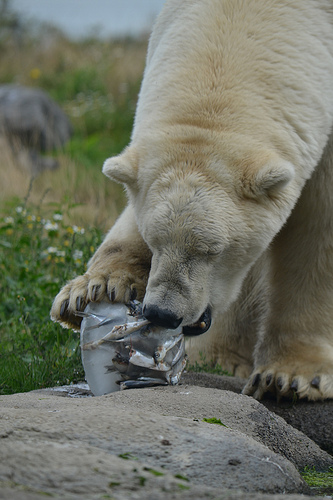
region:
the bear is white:
[59, 5, 314, 314]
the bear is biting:
[38, 228, 236, 390]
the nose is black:
[140, 297, 182, 334]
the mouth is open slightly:
[122, 284, 234, 349]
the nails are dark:
[42, 263, 140, 341]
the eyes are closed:
[109, 219, 235, 277]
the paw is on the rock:
[227, 340, 327, 415]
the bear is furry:
[113, 5, 302, 283]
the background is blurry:
[13, 8, 132, 146]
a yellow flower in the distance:
[9, 51, 57, 89]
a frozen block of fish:
[78, 301, 193, 394]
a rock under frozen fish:
[1, 371, 332, 498]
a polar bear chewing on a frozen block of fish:
[49, 5, 330, 396]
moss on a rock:
[200, 414, 228, 429]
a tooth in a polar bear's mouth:
[199, 319, 209, 331]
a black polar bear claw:
[87, 283, 101, 302]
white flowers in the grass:
[43, 210, 86, 257]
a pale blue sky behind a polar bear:
[7, 1, 166, 37]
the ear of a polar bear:
[97, 148, 141, 187]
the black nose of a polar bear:
[140, 301, 183, 328]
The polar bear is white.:
[45, 11, 325, 389]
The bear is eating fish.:
[43, 266, 235, 432]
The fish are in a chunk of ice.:
[48, 276, 224, 422]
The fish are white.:
[75, 263, 210, 429]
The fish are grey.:
[47, 265, 213, 437]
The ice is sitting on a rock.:
[12, 352, 326, 488]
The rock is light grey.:
[14, 374, 321, 499]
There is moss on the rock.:
[281, 440, 329, 498]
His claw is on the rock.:
[217, 362, 330, 405]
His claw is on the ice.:
[28, 267, 172, 330]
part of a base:
[97, 370, 122, 395]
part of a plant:
[302, 459, 320, 484]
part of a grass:
[33, 349, 74, 396]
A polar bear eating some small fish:
[42, 35, 332, 490]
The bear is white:
[78, 7, 311, 388]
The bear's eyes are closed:
[137, 230, 243, 280]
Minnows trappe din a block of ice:
[80, 293, 188, 393]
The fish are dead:
[102, 314, 188, 399]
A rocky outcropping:
[61, 393, 323, 498]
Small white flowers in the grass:
[44, 204, 70, 262]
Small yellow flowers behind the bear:
[60, 219, 77, 258]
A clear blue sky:
[56, 0, 137, 25]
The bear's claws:
[51, 282, 139, 316]